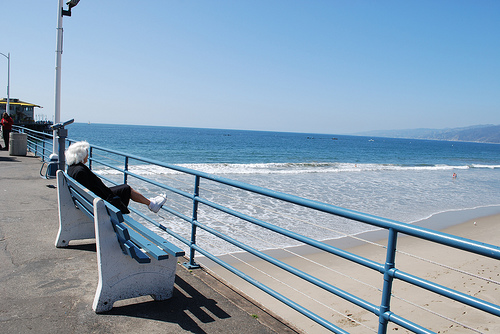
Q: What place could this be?
A: It is an ocean.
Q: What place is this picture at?
A: It is at the ocean.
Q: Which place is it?
A: It is an ocean.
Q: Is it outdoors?
A: Yes, it is outdoors.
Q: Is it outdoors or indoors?
A: It is outdoors.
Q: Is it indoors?
A: No, it is outdoors.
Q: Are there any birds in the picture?
A: No, there are no birds.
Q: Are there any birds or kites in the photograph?
A: No, there are no birds or kites.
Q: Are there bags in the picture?
A: No, there are no bags.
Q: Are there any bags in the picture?
A: No, there are no bags.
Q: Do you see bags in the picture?
A: No, there are no bags.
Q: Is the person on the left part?
A: Yes, the person is on the left of the image.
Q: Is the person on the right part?
A: No, the person is on the left of the image.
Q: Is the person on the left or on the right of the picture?
A: The person is on the left of the image.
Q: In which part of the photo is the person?
A: The person is on the left of the image.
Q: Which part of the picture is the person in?
A: The person is on the left of the image.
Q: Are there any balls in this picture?
A: No, there are no balls.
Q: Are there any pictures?
A: No, there are no pictures.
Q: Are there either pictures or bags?
A: No, there are no pictures or bags.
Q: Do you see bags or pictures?
A: No, there are no pictures or bags.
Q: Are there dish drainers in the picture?
A: No, there are no dish drainers.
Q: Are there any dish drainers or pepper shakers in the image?
A: No, there are no dish drainers or pepper shakers.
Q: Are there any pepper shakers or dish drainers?
A: No, there are no dish drainers or pepper shakers.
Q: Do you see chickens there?
A: No, there are no chickens.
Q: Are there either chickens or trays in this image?
A: No, there are no chickens or trays.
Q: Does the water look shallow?
A: Yes, the water is shallow.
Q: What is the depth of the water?
A: The water is shallow.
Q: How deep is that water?
A: The water is shallow.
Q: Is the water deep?
A: No, the water is shallow.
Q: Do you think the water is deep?
A: No, the water is shallow.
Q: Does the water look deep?
A: No, the water is shallow.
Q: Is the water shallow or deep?
A: The water is shallow.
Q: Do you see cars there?
A: No, there are no cars.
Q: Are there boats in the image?
A: No, there are no boats.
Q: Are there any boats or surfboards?
A: No, there are no boats or surfboards.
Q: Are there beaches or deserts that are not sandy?
A: No, there is a beach but it is sandy.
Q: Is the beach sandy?
A: Yes, the beach is sandy.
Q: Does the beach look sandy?
A: Yes, the beach is sandy.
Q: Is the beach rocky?
A: No, the beach is sandy.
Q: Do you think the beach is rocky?
A: No, the beach is sandy.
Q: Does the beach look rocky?
A: No, the beach is sandy.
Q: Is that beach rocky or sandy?
A: The beach is sandy.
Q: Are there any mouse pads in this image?
A: No, there are no mouse pads.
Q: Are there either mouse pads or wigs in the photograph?
A: No, there are no mouse pads or wigs.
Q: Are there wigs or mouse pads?
A: No, there are no mouse pads or wigs.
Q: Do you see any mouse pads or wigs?
A: No, there are no mouse pads or wigs.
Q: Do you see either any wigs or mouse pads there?
A: No, there are no mouse pads or wigs.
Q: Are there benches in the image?
A: Yes, there is a bench.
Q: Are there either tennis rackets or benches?
A: Yes, there is a bench.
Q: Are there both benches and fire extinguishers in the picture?
A: No, there is a bench but no fire extinguishers.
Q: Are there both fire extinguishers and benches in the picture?
A: No, there is a bench but no fire extinguishers.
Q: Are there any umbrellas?
A: No, there are no umbrellas.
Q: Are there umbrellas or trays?
A: No, there are no umbrellas or trays.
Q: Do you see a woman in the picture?
A: Yes, there is a woman.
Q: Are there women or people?
A: Yes, there is a woman.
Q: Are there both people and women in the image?
A: Yes, there are both a woman and a person.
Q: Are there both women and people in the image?
A: Yes, there are both a woman and a person.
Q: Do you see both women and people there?
A: Yes, there are both a woman and a person.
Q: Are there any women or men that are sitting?
A: Yes, the woman is sitting.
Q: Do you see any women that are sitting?
A: Yes, there is a woman that is sitting.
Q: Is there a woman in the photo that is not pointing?
A: Yes, there is a woman that is sitting.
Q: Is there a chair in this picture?
A: No, there are no chairs.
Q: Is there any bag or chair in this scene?
A: No, there are no chairs or bags.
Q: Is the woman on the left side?
A: Yes, the woman is on the left of the image.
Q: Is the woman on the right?
A: No, the woman is on the left of the image.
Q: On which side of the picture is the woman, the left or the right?
A: The woman is on the left of the image.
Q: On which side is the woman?
A: The woman is on the left of the image.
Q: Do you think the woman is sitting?
A: Yes, the woman is sitting.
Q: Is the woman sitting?
A: Yes, the woman is sitting.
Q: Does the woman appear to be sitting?
A: Yes, the woman is sitting.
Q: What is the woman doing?
A: The woman is sitting.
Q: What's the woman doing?
A: The woman is sitting.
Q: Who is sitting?
A: The woman is sitting.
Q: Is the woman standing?
A: No, the woman is sitting.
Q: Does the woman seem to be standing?
A: No, the woman is sitting.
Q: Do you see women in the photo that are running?
A: No, there is a woman but she is sitting.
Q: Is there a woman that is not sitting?
A: No, there is a woman but she is sitting.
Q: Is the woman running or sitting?
A: The woman is sitting.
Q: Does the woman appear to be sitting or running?
A: The woman is sitting.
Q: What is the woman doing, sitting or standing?
A: The woman is sitting.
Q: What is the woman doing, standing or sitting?
A: The woman is sitting.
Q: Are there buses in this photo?
A: No, there are no buses.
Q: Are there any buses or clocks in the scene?
A: No, there are no buses or clocks.